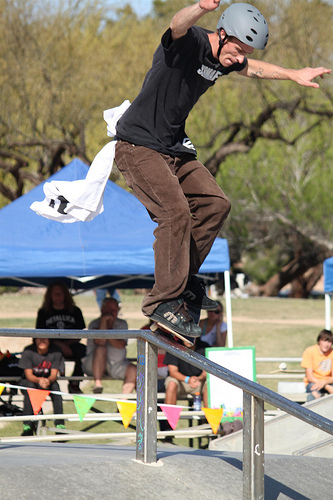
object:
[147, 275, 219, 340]
shoes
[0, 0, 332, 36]
sky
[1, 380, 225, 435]
colorful banner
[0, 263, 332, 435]
people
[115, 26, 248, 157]
t-shirt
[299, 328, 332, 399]
boy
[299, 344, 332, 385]
shirt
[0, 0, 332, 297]
trees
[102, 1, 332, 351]
boy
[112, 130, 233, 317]
brown pants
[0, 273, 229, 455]
bleachers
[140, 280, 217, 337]
sneakers